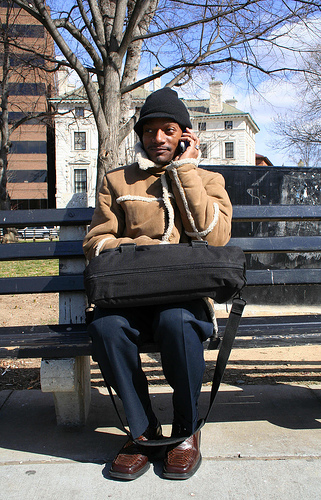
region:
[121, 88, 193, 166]
man holding a cell phone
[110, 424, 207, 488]
man wearing brown shoes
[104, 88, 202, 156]
man wearing black hat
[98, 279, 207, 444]
man wearing blue pants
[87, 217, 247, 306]
large black laptop bag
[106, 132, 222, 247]
white and brown jacket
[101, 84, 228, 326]
man sitting on park bench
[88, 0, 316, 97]
tree with no leaves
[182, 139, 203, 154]
ring on a finger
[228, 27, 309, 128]
white clouds in sky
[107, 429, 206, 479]
dark brown leather shoes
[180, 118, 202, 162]
man talking on cellphone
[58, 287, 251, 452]
strap to his bag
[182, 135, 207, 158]
man has ring on left hand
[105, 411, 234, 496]
man's shoes are squar toed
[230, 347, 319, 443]
shadows on the ground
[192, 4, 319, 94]
tree doesn't have leaves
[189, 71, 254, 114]
building has chimneys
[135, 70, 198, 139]
man wearing a black hat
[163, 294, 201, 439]
man's pants have crease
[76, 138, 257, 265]
man wearing a jacket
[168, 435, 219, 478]
right brown dress shoe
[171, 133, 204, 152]
cell phone next to man's ear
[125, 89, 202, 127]
black winter stocking cap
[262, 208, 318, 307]
dark black wooden outdoor bench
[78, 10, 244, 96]
leafless tree in winter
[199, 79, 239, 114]
white chimney on right of white house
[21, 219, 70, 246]
white car parked in front of building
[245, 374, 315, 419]
dark shadow of park bench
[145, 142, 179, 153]
dark black mustache located over his lip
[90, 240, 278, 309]
black suitcase sitting on man's lap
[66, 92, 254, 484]
a man sitting on a park bench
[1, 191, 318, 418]
a concrete and black painted bench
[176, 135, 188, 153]
a cellular phone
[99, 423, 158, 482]
a brown man's shoe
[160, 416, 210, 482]
a brown man's shoe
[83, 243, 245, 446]
a large black leather bag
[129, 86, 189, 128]
a black winter cap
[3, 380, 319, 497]
a white paved sidewalk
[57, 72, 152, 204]
a white building in distance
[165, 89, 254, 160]
a white building in distance